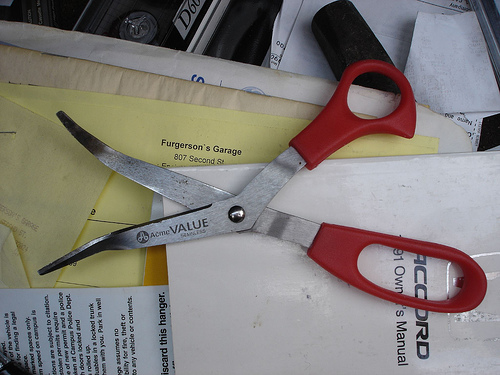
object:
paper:
[401, 5, 498, 121]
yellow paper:
[0, 79, 439, 293]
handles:
[290, 60, 416, 172]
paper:
[0, 42, 159, 292]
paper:
[161, 147, 500, 374]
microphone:
[292, 58, 420, 202]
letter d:
[177, 8, 193, 29]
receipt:
[1, 84, 440, 288]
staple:
[1, 130, 17, 135]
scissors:
[36, 61, 490, 312]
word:
[387, 317, 413, 374]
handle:
[306, 221, 488, 313]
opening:
[249, 63, 489, 313]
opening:
[335, 62, 418, 143]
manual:
[180, 265, 348, 358]